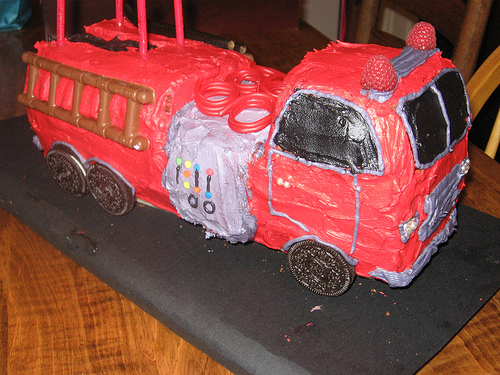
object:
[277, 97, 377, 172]
window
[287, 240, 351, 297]
wheel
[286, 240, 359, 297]
cookie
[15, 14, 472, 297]
frosting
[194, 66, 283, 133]
licorice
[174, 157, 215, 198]
buttons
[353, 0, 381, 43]
brown chair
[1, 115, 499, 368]
platform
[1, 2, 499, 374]
table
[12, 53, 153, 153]
frosting ladder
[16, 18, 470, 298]
fire truck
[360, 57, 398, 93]
berry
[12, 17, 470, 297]
cake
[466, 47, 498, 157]
chair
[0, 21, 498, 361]
scene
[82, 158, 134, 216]
wheel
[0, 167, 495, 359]
plate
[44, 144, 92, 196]
tires